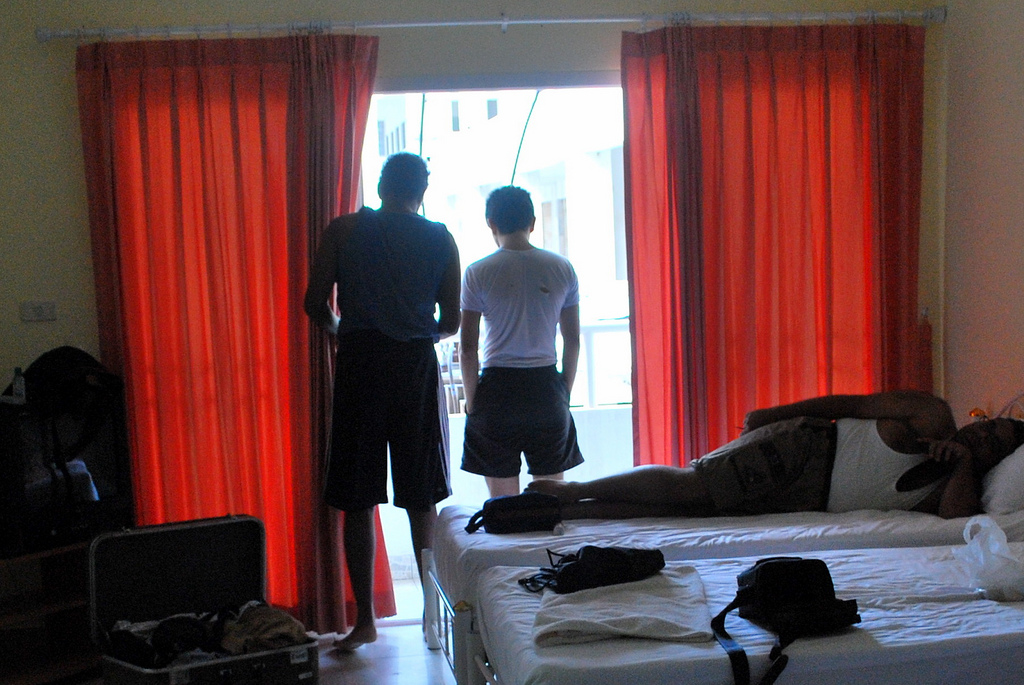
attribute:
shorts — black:
[457, 350, 568, 521]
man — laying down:
[478, 390, 1019, 533]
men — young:
[252, 106, 641, 539]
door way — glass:
[403, 106, 656, 459]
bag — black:
[686, 556, 857, 680]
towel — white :
[535, 569, 717, 639]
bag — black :
[669, 532, 858, 667]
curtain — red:
[623, 19, 930, 467]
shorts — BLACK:
[316, 336, 457, 499]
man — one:
[491, 389, 1012, 511]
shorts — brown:
[681, 400, 831, 511]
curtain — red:
[72, 46, 956, 470]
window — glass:
[340, 93, 732, 467]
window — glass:
[284, 87, 688, 487]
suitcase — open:
[61, 482, 351, 677]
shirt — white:
[471, 253, 577, 370]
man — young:
[454, 160, 597, 489]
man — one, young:
[459, 176, 596, 499]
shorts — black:
[458, 355, 592, 466]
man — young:
[458, 188, 603, 467]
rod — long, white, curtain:
[52, 7, 990, 42]